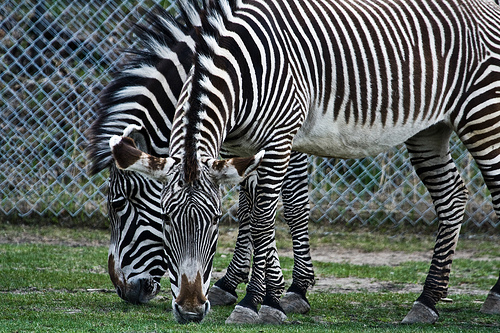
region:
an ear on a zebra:
[200, 141, 281, 183]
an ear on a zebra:
[99, 131, 182, 182]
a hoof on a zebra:
[220, 299, 272, 331]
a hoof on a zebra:
[198, 270, 247, 307]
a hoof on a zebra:
[252, 287, 295, 329]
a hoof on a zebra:
[272, 273, 322, 318]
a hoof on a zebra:
[398, 288, 447, 331]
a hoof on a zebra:
[475, 281, 498, 317]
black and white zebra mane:
[62, 2, 218, 179]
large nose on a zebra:
[168, 275, 215, 328]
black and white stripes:
[284, 22, 403, 106]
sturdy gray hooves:
[231, 307, 307, 329]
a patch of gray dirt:
[330, 272, 391, 296]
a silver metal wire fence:
[14, 15, 94, 200]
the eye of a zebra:
[158, 205, 196, 230]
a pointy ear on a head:
[106, 132, 161, 176]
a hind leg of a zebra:
[429, 162, 459, 308]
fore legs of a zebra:
[244, 182, 309, 315]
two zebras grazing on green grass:
[106, 48, 493, 316]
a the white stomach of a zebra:
[320, 115, 405, 158]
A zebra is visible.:
[104, 46, 379, 264]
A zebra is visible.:
[194, 106, 386, 297]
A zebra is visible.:
[118, 83, 299, 307]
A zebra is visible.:
[185, 168, 322, 308]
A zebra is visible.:
[208, 221, 268, 293]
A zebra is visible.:
[191, 192, 268, 280]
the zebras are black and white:
[92, 1, 493, 328]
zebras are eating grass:
[58, 88, 322, 325]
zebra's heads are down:
[74, 64, 325, 329]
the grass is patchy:
[277, 222, 492, 316]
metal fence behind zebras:
[1, 1, 486, 281]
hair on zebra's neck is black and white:
[52, 2, 269, 153]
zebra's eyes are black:
[142, 201, 237, 241]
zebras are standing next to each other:
[60, 0, 471, 328]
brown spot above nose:
[177, 271, 212, 311]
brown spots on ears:
[88, 107, 290, 191]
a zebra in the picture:
[141, 0, 498, 331]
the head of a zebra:
[93, 136, 259, 331]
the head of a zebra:
[99, 137, 177, 304]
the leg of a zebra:
[246, 130, 293, 322]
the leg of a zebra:
[279, 147, 326, 322]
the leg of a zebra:
[402, 122, 471, 332]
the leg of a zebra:
[449, 95, 499, 317]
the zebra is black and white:
[105, 0, 497, 332]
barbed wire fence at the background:
[2, 2, 499, 236]